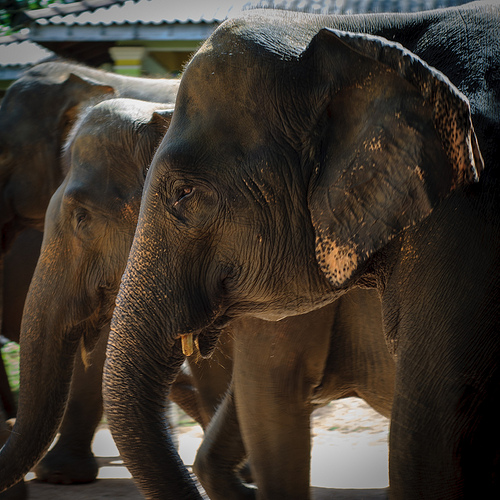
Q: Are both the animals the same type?
A: Yes, all the animals are elephants.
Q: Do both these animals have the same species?
A: Yes, all the animals are elephants.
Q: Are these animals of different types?
A: No, all the animals are elephants.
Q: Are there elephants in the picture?
A: Yes, there is an elephant.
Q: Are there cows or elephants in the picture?
A: Yes, there is an elephant.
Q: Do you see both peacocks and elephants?
A: No, there is an elephant but no peacocks.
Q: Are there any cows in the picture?
A: No, there are no cows.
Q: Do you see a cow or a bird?
A: No, there are no cows or birds.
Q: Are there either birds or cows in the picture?
A: No, there are no cows or birds.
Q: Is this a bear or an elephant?
A: This is an elephant.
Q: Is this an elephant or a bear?
A: This is an elephant.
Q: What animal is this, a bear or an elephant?
A: This is an elephant.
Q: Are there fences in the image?
A: No, there are no fences.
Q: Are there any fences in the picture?
A: No, there are no fences.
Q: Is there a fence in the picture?
A: No, there are no fences.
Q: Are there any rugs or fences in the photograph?
A: No, there are no fences or rugs.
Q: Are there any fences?
A: No, there are no fences.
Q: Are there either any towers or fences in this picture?
A: No, there are no fences or towers.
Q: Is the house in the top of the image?
A: Yes, the house is in the top of the image.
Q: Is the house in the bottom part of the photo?
A: No, the house is in the top of the image.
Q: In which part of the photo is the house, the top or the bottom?
A: The house is in the top of the image.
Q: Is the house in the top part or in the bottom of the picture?
A: The house is in the top of the image.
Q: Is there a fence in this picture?
A: No, there are no fences.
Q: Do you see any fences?
A: No, there are no fences.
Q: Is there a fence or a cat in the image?
A: No, there are no fences or cats.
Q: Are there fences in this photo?
A: No, there are no fences.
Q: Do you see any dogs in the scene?
A: No, there are no dogs.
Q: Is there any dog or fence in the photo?
A: No, there are no dogs or fences.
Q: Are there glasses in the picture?
A: No, there are no glasses.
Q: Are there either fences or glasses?
A: No, there are no glasses or fences.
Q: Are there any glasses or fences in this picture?
A: No, there are no glasses or fences.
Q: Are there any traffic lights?
A: No, there are no traffic lights.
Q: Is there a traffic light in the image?
A: No, there are no traffic lights.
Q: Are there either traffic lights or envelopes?
A: No, there are no traffic lights or envelopes.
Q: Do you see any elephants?
A: Yes, there is an elephant.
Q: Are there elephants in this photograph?
A: Yes, there is an elephant.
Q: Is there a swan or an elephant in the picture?
A: Yes, there is an elephant.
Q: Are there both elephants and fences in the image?
A: No, there is an elephant but no fences.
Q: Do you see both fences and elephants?
A: No, there is an elephant but no fences.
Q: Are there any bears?
A: No, there are no bears.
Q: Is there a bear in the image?
A: No, there are no bears.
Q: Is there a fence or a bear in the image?
A: No, there are no bears or fences.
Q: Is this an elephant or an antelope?
A: This is an elephant.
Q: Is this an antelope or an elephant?
A: This is an elephant.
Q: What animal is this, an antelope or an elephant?
A: This is an elephant.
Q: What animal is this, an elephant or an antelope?
A: This is an elephant.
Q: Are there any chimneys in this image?
A: No, there are no chimneys.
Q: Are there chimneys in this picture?
A: No, there are no chimneys.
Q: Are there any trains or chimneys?
A: No, there are no chimneys or trains.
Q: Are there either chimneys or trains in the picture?
A: No, there are no chimneys or trains.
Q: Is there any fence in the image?
A: No, there are no fences.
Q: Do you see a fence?
A: No, there are no fences.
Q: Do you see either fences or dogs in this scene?
A: No, there are no fences or dogs.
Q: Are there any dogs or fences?
A: No, there are no fences or dogs.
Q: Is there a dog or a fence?
A: No, there are no fences or dogs.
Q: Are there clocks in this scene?
A: No, there are no clocks.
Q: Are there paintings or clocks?
A: No, there are no clocks or paintings.